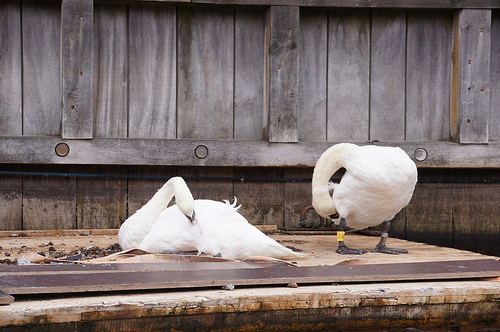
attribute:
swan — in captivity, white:
[307, 139, 422, 254]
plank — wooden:
[235, 9, 269, 143]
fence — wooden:
[2, 0, 497, 168]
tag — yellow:
[338, 232, 346, 245]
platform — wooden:
[3, 223, 498, 331]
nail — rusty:
[469, 59, 473, 65]